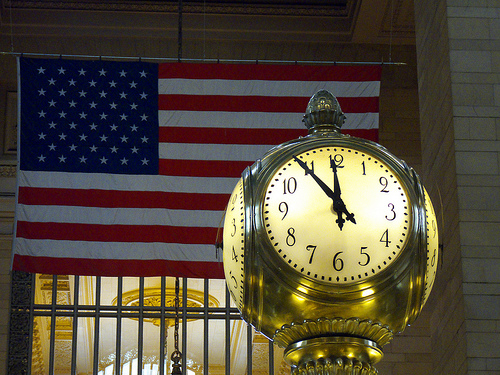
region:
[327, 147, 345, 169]
black number on clock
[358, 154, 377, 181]
black number on clock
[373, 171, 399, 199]
black number on clock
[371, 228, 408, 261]
black number on clock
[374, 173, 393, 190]
black number on clock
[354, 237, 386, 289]
black number on clock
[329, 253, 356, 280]
black number on clock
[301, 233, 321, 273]
black number on clock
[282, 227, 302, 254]
black number on clock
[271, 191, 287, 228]
black number on clock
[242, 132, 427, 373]
this is a clock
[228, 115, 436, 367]
the clock is glowing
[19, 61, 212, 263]
this is the flag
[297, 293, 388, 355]
the clock is golden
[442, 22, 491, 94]
this is a pillar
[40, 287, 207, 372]
this is a gate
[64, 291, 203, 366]
the gate is metallic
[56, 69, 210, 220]
this is a flag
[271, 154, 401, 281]
this is a clock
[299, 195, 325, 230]
the clock is white in color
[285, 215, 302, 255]
the writing is in black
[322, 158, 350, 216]
this is the hour hand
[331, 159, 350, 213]
the hand is black in color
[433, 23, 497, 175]
this is a wall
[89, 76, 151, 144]
these are the clouds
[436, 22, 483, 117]
the wall is brown in color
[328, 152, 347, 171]
Number 12 on a clock.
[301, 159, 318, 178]
Number 11 on a clock.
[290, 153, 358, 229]
Both black hands on a clock.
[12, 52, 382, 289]
A large American flag hanging.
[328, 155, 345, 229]
Small black hand on a clock.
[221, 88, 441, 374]
A metal pole with round top holding 3 visible clocks.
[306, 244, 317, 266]
The number 7 on the front faced clock.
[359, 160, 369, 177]
The number 1 on the front faced clock by the 12.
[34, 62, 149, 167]
Section of white stars on the blue background of the flag.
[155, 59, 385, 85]
Top red stripe on the American flag.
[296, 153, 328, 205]
Black hand on clock.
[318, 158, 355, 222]
Black hand on clock.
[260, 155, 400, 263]
Black numbers on clock.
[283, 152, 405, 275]
Face of clock is round.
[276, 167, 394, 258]
Face of clock is illuminated.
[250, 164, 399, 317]
Clock is in gold stand.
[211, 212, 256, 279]
Black numbers on clock.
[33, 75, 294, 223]
American flag behind clock.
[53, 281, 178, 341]
Metal bars under flag.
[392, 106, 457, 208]
Flag is near brown building.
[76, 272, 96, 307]
glass window on the building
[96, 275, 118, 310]
glass window on the building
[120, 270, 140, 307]
glass window on the building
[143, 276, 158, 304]
glass window on the building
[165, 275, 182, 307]
glass window on the building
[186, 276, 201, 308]
glass window on the building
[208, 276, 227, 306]
glass window on the building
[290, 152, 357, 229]
black minute and hour hands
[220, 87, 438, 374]
shiny silver clock with three faces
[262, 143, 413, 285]
white clock face with black numbers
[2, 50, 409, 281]
flag hanging on white pole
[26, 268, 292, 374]
silver metal bars covering inside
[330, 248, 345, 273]
black number 6